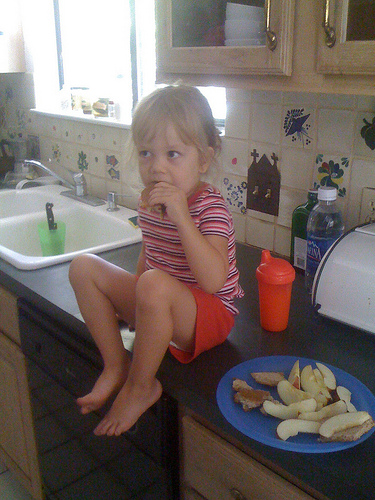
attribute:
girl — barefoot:
[54, 80, 240, 456]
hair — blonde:
[117, 79, 234, 170]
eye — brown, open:
[132, 145, 157, 163]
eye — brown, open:
[165, 148, 183, 162]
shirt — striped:
[128, 180, 255, 315]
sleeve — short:
[197, 196, 234, 241]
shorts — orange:
[127, 270, 239, 368]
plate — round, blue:
[210, 351, 374, 461]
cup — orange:
[244, 246, 302, 336]